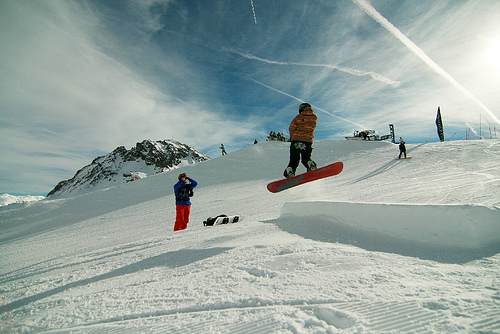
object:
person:
[281, 101, 320, 180]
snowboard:
[198, 210, 245, 228]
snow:
[0, 139, 500, 333]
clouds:
[0, 35, 257, 194]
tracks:
[66, 255, 188, 331]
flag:
[430, 103, 448, 145]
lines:
[246, 76, 373, 130]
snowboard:
[264, 159, 344, 194]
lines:
[50, 290, 361, 331]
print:
[293, 304, 338, 332]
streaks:
[238, 48, 406, 90]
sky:
[0, 0, 500, 195]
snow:
[47, 137, 213, 197]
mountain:
[42, 135, 214, 198]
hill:
[214, 135, 287, 170]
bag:
[203, 210, 244, 228]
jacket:
[287, 111, 321, 145]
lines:
[297, 118, 315, 124]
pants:
[172, 201, 192, 231]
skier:
[216, 140, 229, 154]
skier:
[261, 96, 347, 204]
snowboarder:
[263, 98, 346, 194]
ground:
[0, 228, 500, 334]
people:
[171, 171, 199, 232]